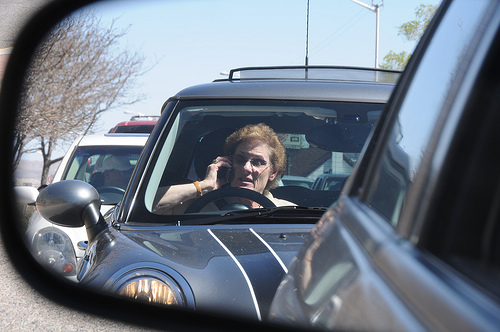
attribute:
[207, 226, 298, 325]
stripe — Black 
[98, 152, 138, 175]
hat — white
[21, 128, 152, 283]
car — white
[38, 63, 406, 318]
car — gray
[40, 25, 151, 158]
branches — bare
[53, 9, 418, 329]
mirror — reflecting